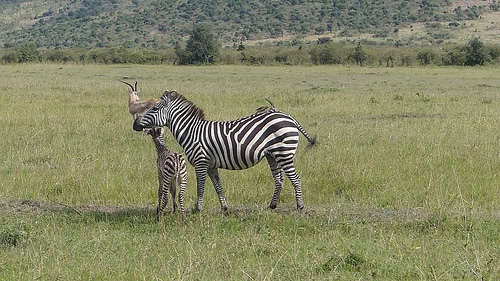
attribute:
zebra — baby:
[148, 127, 189, 215]